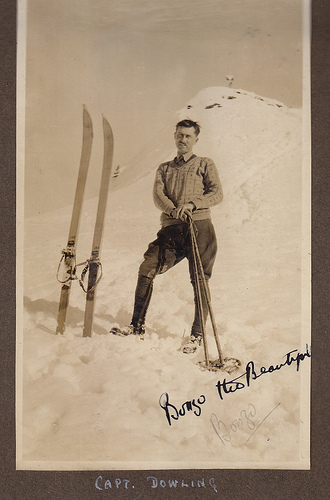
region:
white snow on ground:
[57, 376, 78, 400]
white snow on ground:
[57, 423, 88, 449]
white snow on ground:
[101, 413, 137, 449]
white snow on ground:
[127, 395, 146, 415]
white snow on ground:
[138, 358, 160, 379]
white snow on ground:
[130, 341, 151, 372]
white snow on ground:
[256, 317, 277, 343]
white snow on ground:
[51, 346, 77, 371]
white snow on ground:
[30, 326, 55, 355]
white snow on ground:
[101, 346, 129, 370]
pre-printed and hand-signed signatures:
[155, 336, 306, 462]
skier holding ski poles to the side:
[148, 112, 235, 372]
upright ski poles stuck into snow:
[47, 99, 93, 341]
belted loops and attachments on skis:
[50, 239, 101, 292]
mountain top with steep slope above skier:
[24, 73, 298, 158]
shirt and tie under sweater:
[149, 149, 219, 220]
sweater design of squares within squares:
[148, 156, 221, 219]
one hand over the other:
[156, 199, 197, 222]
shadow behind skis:
[21, 288, 149, 338]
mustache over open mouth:
[170, 116, 199, 150]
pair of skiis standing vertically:
[57, 104, 116, 343]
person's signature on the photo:
[157, 344, 313, 432]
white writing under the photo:
[93, 474, 220, 496]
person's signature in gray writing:
[204, 388, 299, 454]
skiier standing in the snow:
[110, 117, 247, 373]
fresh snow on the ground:
[17, 222, 301, 456]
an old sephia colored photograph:
[11, 0, 310, 470]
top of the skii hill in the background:
[114, 86, 305, 178]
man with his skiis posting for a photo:
[52, 101, 241, 376]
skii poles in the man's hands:
[185, 213, 228, 370]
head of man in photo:
[167, 117, 207, 158]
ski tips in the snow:
[200, 357, 237, 376]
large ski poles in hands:
[179, 218, 228, 362]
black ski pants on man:
[122, 223, 215, 334]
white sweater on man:
[144, 158, 214, 218]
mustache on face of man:
[173, 138, 189, 150]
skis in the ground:
[50, 110, 111, 346]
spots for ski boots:
[51, 242, 100, 306]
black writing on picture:
[143, 343, 303, 427]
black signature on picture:
[145, 344, 309, 430]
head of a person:
[175, 112, 209, 154]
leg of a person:
[106, 323, 152, 340]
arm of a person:
[158, 170, 179, 217]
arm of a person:
[192, 176, 238, 214]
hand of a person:
[169, 195, 188, 220]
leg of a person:
[122, 227, 171, 303]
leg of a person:
[182, 259, 222, 329]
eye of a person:
[175, 124, 186, 143]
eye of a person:
[187, 133, 191, 142]